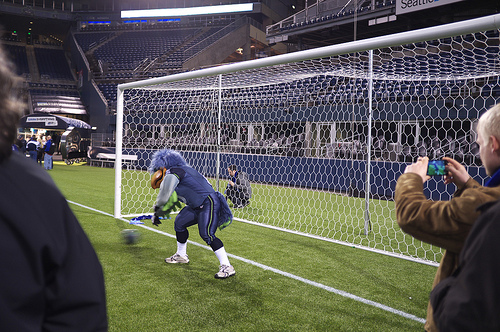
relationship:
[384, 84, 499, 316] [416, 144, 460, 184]
man holding cellphone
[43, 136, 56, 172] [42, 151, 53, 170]
man wearing jeans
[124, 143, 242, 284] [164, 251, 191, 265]
mascot has tennis shoe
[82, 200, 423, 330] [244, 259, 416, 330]
grass has a stripe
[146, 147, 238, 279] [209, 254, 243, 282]
mascot wearing tennis shoe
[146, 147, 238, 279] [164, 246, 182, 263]
mascot wearing tennis shoe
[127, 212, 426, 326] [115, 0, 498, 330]
line near goal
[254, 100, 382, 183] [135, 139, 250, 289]
mesh behind mascot